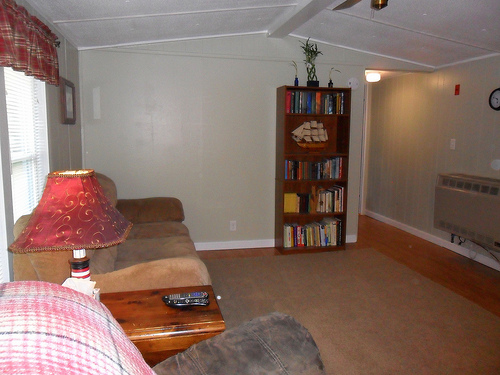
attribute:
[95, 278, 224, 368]
table — wooden, brown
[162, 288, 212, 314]
remote controls —  two, for television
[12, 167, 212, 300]
sofa — brown, tan, beige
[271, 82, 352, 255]
bookshelf — brown, tan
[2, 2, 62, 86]
material — red, white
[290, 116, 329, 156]
ship — replica, decorative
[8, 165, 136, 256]
lampshade — pink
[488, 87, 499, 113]
clock — black, white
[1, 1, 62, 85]
valance — plaid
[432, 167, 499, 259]
heater — for heat and cooling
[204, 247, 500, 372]
rug — brown